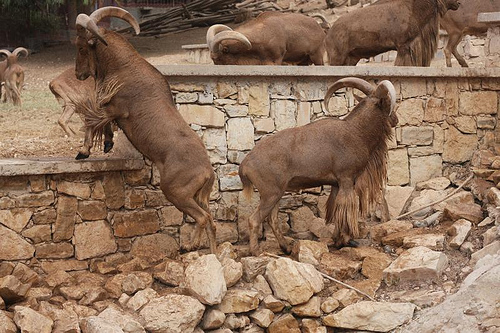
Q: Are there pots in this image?
A: No, there are no pots.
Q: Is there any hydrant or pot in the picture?
A: No, there are no pots or fire hydrants.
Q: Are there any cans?
A: No, there are no cans.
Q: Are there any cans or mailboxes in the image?
A: No, there are no cans or mailboxes.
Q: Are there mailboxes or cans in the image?
A: No, there are no cans or mailboxes.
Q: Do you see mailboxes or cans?
A: No, there are no cans or mailboxes.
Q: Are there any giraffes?
A: No, there are no giraffes.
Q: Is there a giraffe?
A: No, there are no giraffes.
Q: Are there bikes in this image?
A: No, there are no bikes.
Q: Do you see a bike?
A: No, there are no bikes.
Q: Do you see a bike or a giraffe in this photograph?
A: No, there are no bikes or giraffes.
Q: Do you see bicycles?
A: No, there are no bicycles.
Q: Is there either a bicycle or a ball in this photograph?
A: No, there are no bicycles or balls.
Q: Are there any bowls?
A: No, there are no bowls.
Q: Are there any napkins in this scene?
A: No, there are no napkins.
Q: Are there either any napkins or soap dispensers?
A: No, there are no napkins or soap dispensers.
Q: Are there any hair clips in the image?
A: No, there are no hair clips.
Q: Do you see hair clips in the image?
A: No, there are no hair clips.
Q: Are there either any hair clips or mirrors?
A: No, there are no hair clips or mirrors.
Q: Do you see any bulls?
A: No, there are no bulls.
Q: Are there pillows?
A: No, there are no pillows.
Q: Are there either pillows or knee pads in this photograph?
A: No, there are no pillows or knee pads.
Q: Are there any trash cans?
A: No, there are no trash cans.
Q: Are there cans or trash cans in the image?
A: No, there are no trash cans or cans.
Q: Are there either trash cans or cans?
A: No, there are no trash cans or cans.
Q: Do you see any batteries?
A: No, there are no batteries.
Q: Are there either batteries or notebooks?
A: No, there are no batteries or notebooks.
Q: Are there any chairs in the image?
A: No, there are no chairs.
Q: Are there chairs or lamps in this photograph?
A: No, there are no chairs or lamps.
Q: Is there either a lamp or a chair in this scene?
A: No, there are no chairs or lamps.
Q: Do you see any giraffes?
A: No, there are no giraffes.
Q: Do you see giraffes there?
A: No, there are no giraffes.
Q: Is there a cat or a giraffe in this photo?
A: No, there are no giraffes or cats.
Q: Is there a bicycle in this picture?
A: No, there are no bicycles.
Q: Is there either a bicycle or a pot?
A: No, there are no bicycles or pots.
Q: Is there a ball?
A: No, there are no balls.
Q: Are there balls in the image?
A: No, there are no balls.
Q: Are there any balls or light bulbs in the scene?
A: No, there are no balls or light bulbs.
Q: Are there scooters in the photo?
A: No, there are no scooters.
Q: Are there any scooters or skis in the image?
A: No, there are no scooters or skis.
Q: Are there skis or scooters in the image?
A: No, there are no scooters or skis.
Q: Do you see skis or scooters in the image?
A: No, there are no scooters or skis.